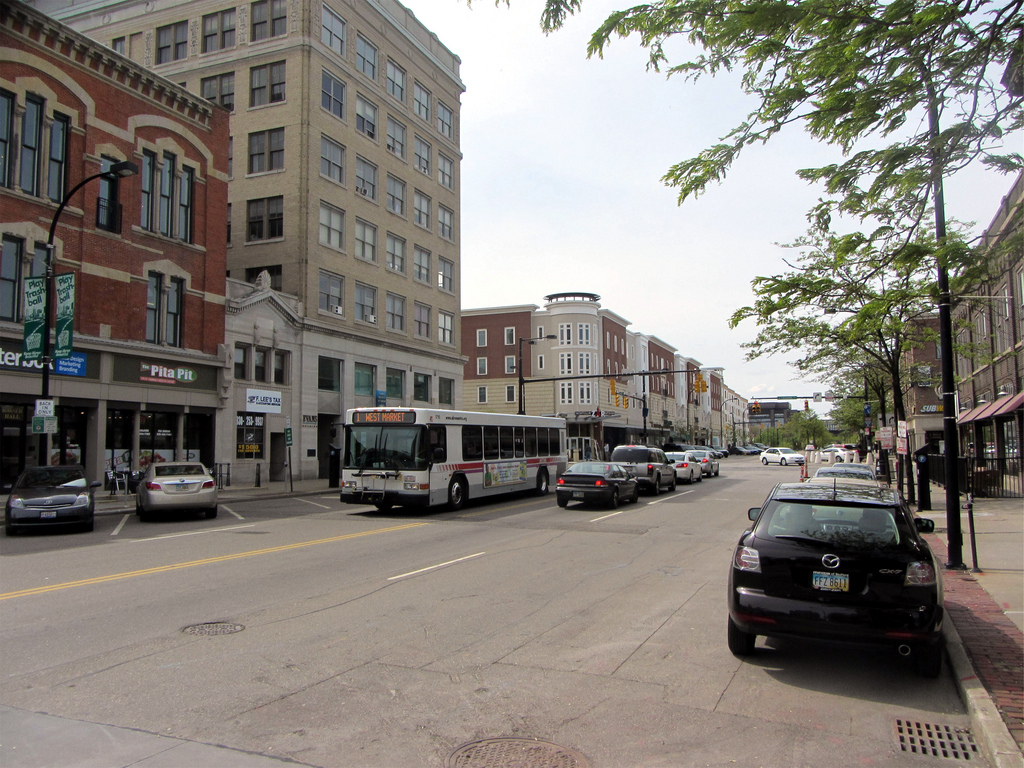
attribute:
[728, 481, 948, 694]
car — parked, black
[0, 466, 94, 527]
car — dark gray, parked